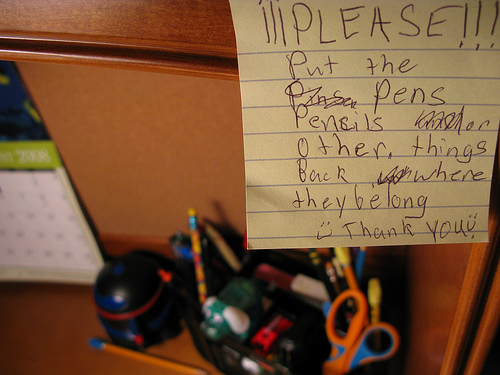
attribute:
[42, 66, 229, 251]
board — back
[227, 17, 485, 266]
paper — yellow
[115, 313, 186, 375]
pencil — sharpener, upright, lying, multi colored, caddy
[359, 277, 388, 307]
eraser — yellow, blue, yelow, small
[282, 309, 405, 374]
holder — black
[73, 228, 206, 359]
bank — piggy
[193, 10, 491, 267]
note — taped, big, thank you, handwritten, child, polite, please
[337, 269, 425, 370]
scissor — blue, orange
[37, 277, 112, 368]
desk — brown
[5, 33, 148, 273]
calender — green, hanging, desk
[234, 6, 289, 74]
mark — exclamation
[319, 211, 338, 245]
face — smiley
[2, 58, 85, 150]
picture — colorful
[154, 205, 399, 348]
supplies — office, desk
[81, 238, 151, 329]
toy — green